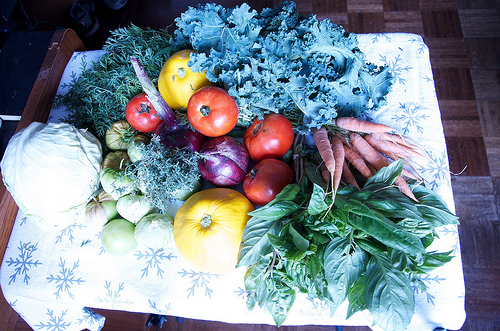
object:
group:
[215, 99, 293, 129]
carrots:
[370, 131, 429, 156]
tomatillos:
[133, 212, 174, 249]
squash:
[172, 187, 257, 276]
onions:
[196, 135, 249, 188]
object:
[8, 28, 61, 128]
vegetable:
[127, 53, 185, 138]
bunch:
[305, 111, 429, 205]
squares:
[420, 10, 465, 39]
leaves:
[322, 234, 369, 309]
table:
[0, 31, 468, 330]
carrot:
[336, 116, 396, 133]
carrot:
[312, 125, 336, 175]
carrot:
[321, 133, 346, 220]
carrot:
[343, 145, 373, 181]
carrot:
[348, 131, 422, 204]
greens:
[364, 253, 416, 331]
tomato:
[186, 85, 239, 137]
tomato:
[124, 92, 164, 133]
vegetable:
[156, 48, 217, 112]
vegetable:
[100, 218, 139, 258]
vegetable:
[115, 193, 156, 226]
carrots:
[363, 134, 433, 163]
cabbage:
[0, 120, 105, 234]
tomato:
[242, 158, 294, 208]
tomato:
[242, 111, 295, 163]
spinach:
[233, 157, 462, 331]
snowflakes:
[46, 256, 87, 302]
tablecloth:
[0, 32, 469, 330]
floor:
[0, 0, 500, 331]